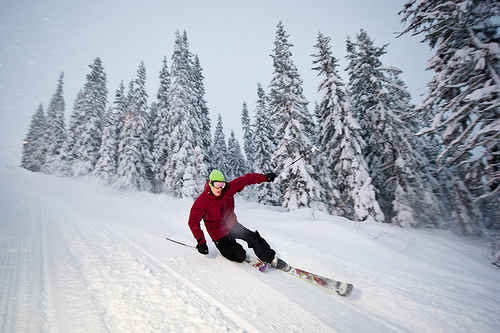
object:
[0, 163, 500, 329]
hillside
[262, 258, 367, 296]
ski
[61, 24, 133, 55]
clouds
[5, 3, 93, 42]
gray sky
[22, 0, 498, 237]
wooded area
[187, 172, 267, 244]
jacket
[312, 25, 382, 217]
trees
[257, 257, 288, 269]
shoes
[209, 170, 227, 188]
hat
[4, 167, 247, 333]
tracks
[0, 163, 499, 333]
snow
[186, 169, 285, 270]
man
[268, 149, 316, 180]
pole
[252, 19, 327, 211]
fir trees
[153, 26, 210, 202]
fir trees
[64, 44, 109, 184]
fir trees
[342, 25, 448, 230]
fir trees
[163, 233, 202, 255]
ski pole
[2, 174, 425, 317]
ski slope